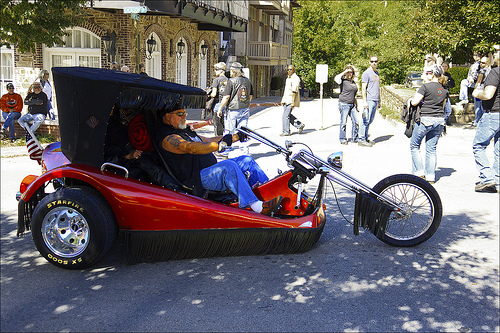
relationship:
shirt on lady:
[417, 82, 448, 123] [405, 63, 449, 182]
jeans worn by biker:
[409, 116, 444, 175] [153, 102, 283, 217]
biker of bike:
[153, 102, 283, 217] [16, 66, 442, 269]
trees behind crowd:
[288, 0, 499, 87] [2, 45, 499, 192]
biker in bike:
[153, 102, 283, 217] [16, 66, 442, 269]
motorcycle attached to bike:
[12, 115, 452, 267] [16, 66, 442, 269]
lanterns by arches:
[145, 33, 208, 56] [145, 24, 213, 91]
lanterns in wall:
[145, 33, 208, 56] [4, 6, 217, 104]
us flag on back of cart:
[24, 119, 45, 159] [16, 68, 443, 266]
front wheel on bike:
[360, 172, 448, 255] [9, 42, 446, 276]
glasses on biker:
[166, 106, 188, 118] [153, 102, 315, 253]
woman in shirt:
[407, 66, 450, 183] [417, 82, 448, 123]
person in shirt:
[334, 64, 361, 145] [340, 77, 355, 107]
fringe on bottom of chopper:
[121, 218, 322, 266] [13, 88, 434, 260]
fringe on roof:
[77, 89, 206, 111] [52, 56, 214, 115]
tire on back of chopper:
[30, 191, 113, 272] [20, 59, 445, 267]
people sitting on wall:
[216, 59, 444, 177] [0, 117, 73, 143]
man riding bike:
[154, 99, 271, 214] [16, 66, 442, 269]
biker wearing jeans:
[153, 102, 283, 217] [200, 152, 268, 209]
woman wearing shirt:
[1, 80, 21, 140] [1, 91, 22, 111]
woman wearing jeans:
[407, 66, 450, 183] [409, 116, 444, 175]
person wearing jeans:
[470, 39, 498, 191] [470, 111, 498, 187]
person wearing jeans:
[330, 59, 361, 145] [338, 99, 358, 140]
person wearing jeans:
[356, 51, 382, 141] [360, 97, 376, 140]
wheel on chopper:
[358, 181, 439, 240] [13, 55, 470, 280]